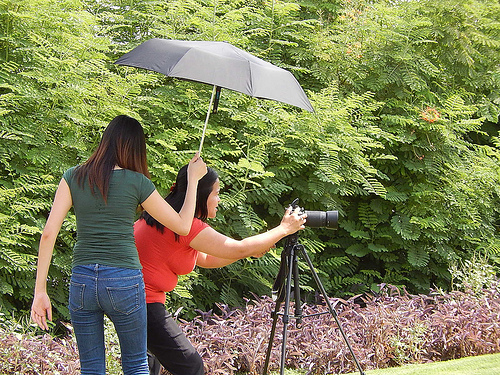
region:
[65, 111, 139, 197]
the head of a woman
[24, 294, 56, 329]
the hand of a woman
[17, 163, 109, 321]
the arm of a woman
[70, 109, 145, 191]
the hair of a woman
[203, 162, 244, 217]
the face of a woman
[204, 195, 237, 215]
the nose of a woman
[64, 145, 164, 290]
the back of a woman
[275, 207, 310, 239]
the fingers of a woman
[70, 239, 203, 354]
a woman wearing jeans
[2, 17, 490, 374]
two women using camera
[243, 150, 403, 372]
camera is on tripod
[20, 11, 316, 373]
woman holding up umbrella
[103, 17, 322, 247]
umbrella is black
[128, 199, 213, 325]
woman wearing red shirt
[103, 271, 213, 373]
woman wearing black pants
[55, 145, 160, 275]
woman wearing green shirt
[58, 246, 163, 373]
woman wearing blue jeans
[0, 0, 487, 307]
green foliage next to woman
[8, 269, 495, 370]
purple flowers on ground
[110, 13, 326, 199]
woman is holding an umbrella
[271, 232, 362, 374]
tripod in the grass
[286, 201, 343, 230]
long lens on the camera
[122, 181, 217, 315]
womanis wearing a red shirt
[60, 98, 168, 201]
woman has long brown hair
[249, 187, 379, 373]
carema is on a tripod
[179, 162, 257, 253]
woman is looking at the camera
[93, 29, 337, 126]
umbrella is black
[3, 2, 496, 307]
bushes are tall and lushes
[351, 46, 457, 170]
Trees are green color.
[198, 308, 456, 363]
Bushes are purple color.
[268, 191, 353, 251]
Camera is black color.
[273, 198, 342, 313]
Camera is on stand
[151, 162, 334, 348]
Woman is taking picture in camera.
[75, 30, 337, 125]
Umbrella is black color.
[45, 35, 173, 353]
Woman is holding umbrella in hand.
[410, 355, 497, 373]
Grass is green color.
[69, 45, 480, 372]
Trees are behind the bushes.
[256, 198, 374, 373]
Camera stand is black color.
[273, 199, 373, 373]
a camera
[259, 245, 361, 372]
a tripod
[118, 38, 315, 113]
a black umberella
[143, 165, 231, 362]
a woman wearing a red shirt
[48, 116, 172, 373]
a woman wearing a green shirt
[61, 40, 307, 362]
a woman holding an umbrella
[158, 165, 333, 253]
a woman holding a camera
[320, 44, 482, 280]
trees and brush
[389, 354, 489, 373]
grass on the ground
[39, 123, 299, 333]
two ladies standing looking at a camera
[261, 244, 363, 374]
The tripod under the camera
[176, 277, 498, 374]
The flowerbed is purple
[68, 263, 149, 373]
The blue jeans on the woman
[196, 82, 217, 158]
The silver pole of the umbrella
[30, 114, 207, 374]
a girl holding an umbrella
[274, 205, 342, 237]
a camera perched on a tri-pod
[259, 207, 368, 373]
a camera and its tri-pod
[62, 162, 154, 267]
a green top on the girl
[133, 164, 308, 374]
a girl taking a photo